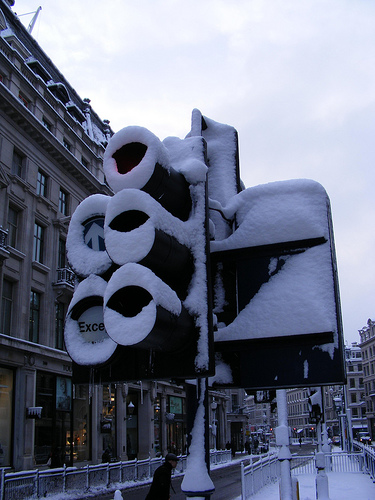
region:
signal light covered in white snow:
[63, 123, 295, 393]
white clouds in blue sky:
[55, 11, 121, 61]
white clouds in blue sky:
[85, 51, 157, 88]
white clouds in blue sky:
[117, 78, 169, 116]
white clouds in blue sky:
[112, 19, 196, 63]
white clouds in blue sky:
[180, 10, 248, 55]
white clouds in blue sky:
[191, 26, 255, 74]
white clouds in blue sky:
[260, 11, 321, 53]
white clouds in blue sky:
[252, 58, 331, 112]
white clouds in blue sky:
[263, 113, 339, 163]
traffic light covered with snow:
[50, 113, 340, 413]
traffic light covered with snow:
[54, 178, 194, 379]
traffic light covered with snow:
[210, 175, 349, 398]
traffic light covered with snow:
[151, 183, 312, 385]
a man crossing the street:
[145, 441, 199, 495]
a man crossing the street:
[142, 433, 232, 498]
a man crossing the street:
[123, 430, 183, 498]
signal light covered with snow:
[212, 167, 344, 405]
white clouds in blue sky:
[96, 69, 151, 107]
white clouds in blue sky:
[143, 24, 192, 54]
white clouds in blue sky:
[112, 59, 174, 98]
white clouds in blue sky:
[274, 114, 319, 154]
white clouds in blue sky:
[304, 40, 347, 127]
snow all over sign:
[54, 105, 350, 380]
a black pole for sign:
[180, 375, 213, 496]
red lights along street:
[264, 427, 318, 435]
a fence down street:
[0, 436, 372, 498]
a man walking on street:
[145, 447, 181, 498]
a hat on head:
[162, 450, 180, 467]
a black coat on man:
[145, 463, 175, 499]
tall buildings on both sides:
[0, 0, 373, 498]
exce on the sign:
[73, 318, 107, 336]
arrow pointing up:
[82, 219, 106, 253]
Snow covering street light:
[54, 120, 341, 385]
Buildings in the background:
[239, 389, 373, 439]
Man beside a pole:
[150, 447, 221, 497]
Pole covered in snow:
[180, 393, 226, 498]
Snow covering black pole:
[179, 377, 232, 497]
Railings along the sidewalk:
[9, 453, 171, 492]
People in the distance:
[220, 431, 276, 460]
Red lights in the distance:
[256, 422, 329, 441]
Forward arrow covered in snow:
[62, 194, 108, 270]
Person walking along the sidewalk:
[38, 435, 141, 470]